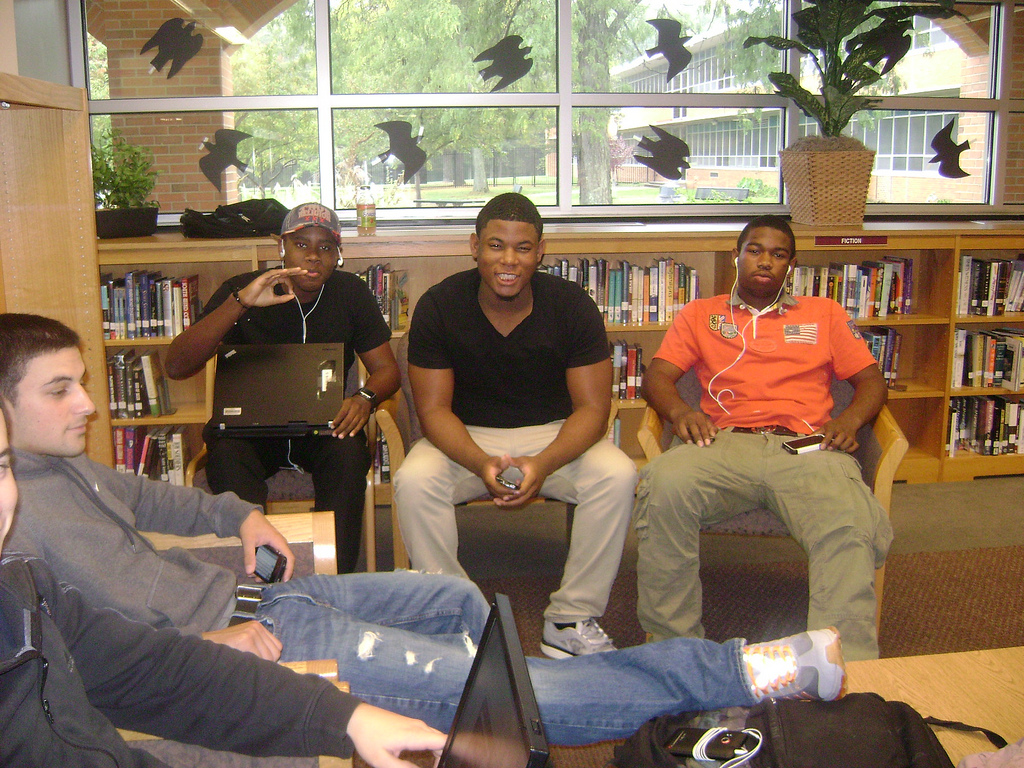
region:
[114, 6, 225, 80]
bat on the window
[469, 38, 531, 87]
bat on the window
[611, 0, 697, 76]
bat on the window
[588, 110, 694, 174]
bat on the window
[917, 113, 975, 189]
bat on the window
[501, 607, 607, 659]
foot of the man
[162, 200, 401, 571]
young man wearing baseball cap and holding laptop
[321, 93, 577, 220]
black paper bird taped to window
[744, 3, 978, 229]
small plant in brown wicker basket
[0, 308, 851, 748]
man wearing grey jacket and blue jeans is holding a cellphone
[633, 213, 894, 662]
man wearing orange shirt with American flag logo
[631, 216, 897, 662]
man wearing white earphones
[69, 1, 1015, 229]
windows with black paper birds inside each one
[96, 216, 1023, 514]
beige wooden shelf ful of books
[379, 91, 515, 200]
a view of trees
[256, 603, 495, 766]
a view of leg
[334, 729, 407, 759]
a view of hand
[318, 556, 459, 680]
marks on the jeans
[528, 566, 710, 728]
a view of shoes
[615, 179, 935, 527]
a view of man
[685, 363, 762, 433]
a view of wire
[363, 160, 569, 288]
face of the person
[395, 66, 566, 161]
a view of plants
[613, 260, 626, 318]
A book on a book shelf.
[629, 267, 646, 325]
A book on a book shelf.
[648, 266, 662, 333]
A book on a book shelf.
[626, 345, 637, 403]
A book on a book shelf.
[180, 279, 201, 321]
A book on a book shelf.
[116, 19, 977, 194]
Black cut-out birds in the window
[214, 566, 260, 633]
A dark colored belt.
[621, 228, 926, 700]
A guy with earphones in his ears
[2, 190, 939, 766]
People sitting down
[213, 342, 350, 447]
A black laptop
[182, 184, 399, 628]
A man with a laptop on his lap.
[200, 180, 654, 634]
Two guys wearing black shirts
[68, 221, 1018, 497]
Shelves of books.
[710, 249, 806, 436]
white headphones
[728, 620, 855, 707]
the shoe of a man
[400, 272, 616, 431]
a man's short sleeve shirt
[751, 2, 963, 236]
a brown potted plant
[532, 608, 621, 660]
the shoe of a boy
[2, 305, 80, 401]
a boy's short cut hair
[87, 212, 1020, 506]
a long brown bookshelf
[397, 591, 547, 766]
the top of a black laptop computer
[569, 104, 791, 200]
a window of a building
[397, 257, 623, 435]
A black short sleeved shirt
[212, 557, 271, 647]
A black leather belt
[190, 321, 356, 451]
A black laptop computer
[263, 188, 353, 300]
A hat on a guy's head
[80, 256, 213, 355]
A row of books on a shelf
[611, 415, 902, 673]
A pair of cargo pants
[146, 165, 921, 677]
Three guys sitting in chairs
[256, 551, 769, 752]
A pair of blue jeans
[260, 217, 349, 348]
Guy wearing white earphones